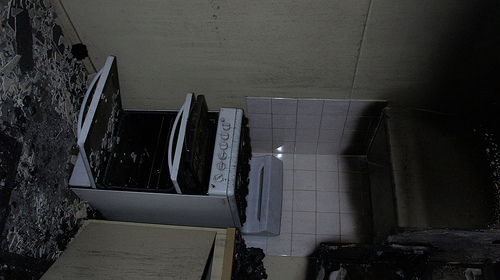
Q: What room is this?
A: A kitchen.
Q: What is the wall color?
A: White tall.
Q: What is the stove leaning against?
A: Wall.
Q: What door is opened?
A: Oven door.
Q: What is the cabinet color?
A: Beige.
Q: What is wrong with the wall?
A: The wall is burnt.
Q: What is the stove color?
A: White.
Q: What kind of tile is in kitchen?
A: White tile.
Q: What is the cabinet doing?
A: It's door is open.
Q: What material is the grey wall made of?
A: Cement.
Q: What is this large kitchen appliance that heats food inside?
A: Oven.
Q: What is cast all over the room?
A: Shadow.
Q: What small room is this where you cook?
A: Kitchen.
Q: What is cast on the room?
A: Shadow.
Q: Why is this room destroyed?
A: Fire.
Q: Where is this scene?
A: Kitchen.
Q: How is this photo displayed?
A: On its side.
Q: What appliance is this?
A: Oven.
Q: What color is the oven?
A: White.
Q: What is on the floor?
A: Debri.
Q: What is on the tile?
A: Soot.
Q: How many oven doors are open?
A: Two.